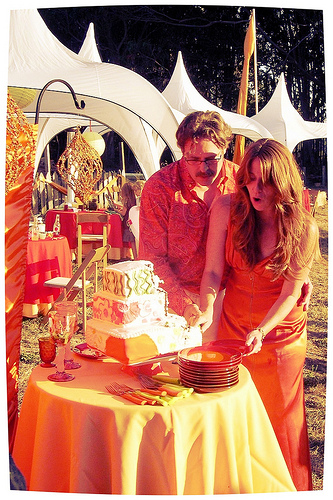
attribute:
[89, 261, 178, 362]
cake — colorful, three layered, white, layered, icing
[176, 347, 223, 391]
plates — orange, stacked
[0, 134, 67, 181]
decor — orange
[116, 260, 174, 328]
wedding cake — uneven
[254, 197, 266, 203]
mouth — open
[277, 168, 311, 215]
hair — long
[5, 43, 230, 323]
reception — wedding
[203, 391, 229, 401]
tablecloth — yellow, red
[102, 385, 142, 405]
forks — orange, gathered, yellow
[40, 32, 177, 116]
tents — white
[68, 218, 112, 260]
chair — wooden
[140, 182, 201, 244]
shirt — paisley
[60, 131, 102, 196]
chandalier — hanging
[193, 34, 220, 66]
forest — green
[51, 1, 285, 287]
scene — wedding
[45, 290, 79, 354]
goblet — tall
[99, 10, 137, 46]
trees — dark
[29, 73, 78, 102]
hook — metal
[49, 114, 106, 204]
structure — diamond shaped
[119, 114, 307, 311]
people — busy